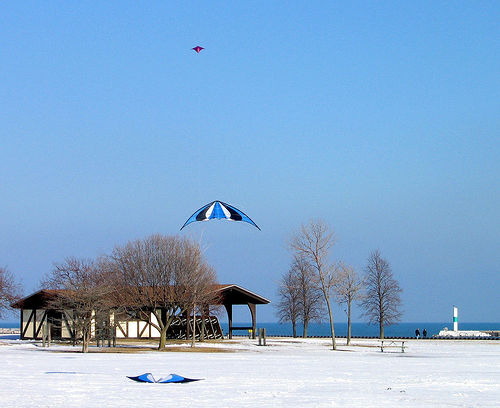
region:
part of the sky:
[381, 155, 453, 216]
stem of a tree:
[319, 314, 345, 371]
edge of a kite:
[211, 200, 245, 214]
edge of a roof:
[233, 277, 277, 312]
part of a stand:
[241, 300, 261, 345]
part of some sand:
[298, 342, 356, 374]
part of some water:
[268, 317, 288, 335]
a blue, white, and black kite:
[176, 194, 263, 236]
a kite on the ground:
[118, 360, 206, 387]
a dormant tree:
[101, 222, 223, 356]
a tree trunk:
[314, 258, 344, 350]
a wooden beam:
[245, 302, 260, 339]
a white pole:
[450, 297, 464, 332]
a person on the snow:
[419, 324, 429, 341]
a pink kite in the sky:
[181, 38, 212, 60]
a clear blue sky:
[1, 0, 499, 322]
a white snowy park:
[1, 340, 496, 407]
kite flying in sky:
[163, 37, 223, 84]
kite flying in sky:
[170, 185, 269, 233]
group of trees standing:
[268, 230, 423, 351]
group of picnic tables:
[167, 314, 227, 351]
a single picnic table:
[367, 336, 419, 360]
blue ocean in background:
[285, 308, 485, 338]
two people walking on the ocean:
[406, 330, 434, 341]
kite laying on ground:
[128, 361, 216, 394]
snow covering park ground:
[217, 345, 449, 396]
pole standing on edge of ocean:
[440, 300, 498, 357]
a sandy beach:
[1, 336, 498, 405]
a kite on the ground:
[123, 371, 203, 385]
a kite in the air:
[178, 199, 258, 230]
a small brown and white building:
[8, 286, 271, 341]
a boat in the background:
[434, 305, 491, 339]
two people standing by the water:
[410, 324, 430, 340]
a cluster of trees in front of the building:
[41, 231, 220, 351]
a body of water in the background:
[1, 321, 499, 342]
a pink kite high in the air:
[189, 41, 206, 54]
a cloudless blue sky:
[1, 2, 499, 323]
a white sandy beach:
[255, 363, 425, 407]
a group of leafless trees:
[285, 221, 399, 339]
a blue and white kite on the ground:
[115, 360, 202, 398]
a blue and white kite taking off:
[172, 178, 287, 240]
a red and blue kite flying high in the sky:
[174, 38, 239, 80]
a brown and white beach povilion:
[17, 277, 274, 349]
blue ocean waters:
[412, 313, 445, 332]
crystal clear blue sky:
[254, 93, 480, 222]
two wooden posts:
[247, 318, 272, 351]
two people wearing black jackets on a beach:
[411, 316, 435, 343]